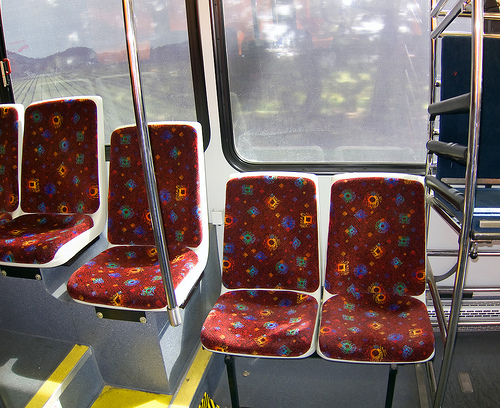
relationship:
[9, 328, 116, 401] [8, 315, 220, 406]
shadow on floor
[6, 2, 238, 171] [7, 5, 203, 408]
rear window to left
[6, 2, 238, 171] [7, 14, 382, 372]
rear window in center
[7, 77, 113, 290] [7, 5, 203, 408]
elevated seats are to left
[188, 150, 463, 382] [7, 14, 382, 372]
two seats are in center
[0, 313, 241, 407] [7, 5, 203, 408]
steps are to left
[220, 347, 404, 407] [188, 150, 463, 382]
legs on two seats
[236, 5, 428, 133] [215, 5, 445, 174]
trees are outside window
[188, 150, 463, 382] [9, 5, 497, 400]
two seats are on train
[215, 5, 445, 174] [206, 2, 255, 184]
window has black frame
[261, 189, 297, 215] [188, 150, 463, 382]
design on two seats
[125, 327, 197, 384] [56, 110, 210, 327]
reflection under seat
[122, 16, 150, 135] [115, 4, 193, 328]
light reflection on pole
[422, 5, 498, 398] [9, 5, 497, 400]
luggage rack on train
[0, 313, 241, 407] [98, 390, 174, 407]
steps are painted yellow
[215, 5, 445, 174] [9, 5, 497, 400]
window on train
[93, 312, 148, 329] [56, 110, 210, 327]
bolts attach seat